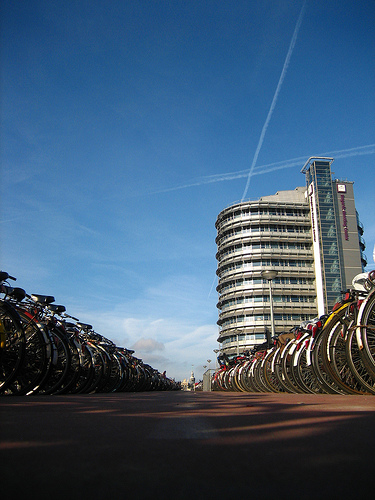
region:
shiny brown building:
[203, 178, 328, 330]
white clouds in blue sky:
[8, 15, 57, 67]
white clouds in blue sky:
[13, 61, 115, 142]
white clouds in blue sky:
[14, 130, 56, 178]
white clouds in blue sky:
[53, 146, 114, 198]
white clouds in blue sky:
[45, 223, 111, 279]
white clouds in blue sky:
[103, 279, 176, 335]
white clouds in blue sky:
[164, 242, 207, 295]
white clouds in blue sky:
[101, 178, 146, 238]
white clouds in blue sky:
[205, 123, 247, 161]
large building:
[212, 179, 319, 306]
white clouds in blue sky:
[13, 70, 46, 105]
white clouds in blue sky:
[121, 253, 173, 300]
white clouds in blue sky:
[150, 295, 196, 355]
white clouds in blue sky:
[94, 294, 145, 327]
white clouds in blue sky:
[43, 151, 89, 200]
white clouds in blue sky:
[150, 186, 182, 228]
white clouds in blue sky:
[170, 116, 235, 147]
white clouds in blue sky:
[234, 74, 299, 114]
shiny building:
[212, 183, 314, 316]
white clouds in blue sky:
[19, 45, 73, 118]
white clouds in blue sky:
[28, 138, 63, 179]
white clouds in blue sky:
[36, 207, 77, 244]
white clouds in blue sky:
[85, 262, 132, 294]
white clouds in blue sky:
[143, 261, 183, 308]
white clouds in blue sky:
[122, 305, 184, 352]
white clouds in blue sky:
[109, 59, 147, 109]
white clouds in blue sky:
[212, 72, 257, 111]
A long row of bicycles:
[1, 270, 179, 402]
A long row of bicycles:
[190, 265, 373, 392]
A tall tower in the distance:
[189, 370, 195, 383]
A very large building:
[214, 155, 368, 368]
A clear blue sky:
[1, 0, 372, 381]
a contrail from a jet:
[237, 5, 305, 202]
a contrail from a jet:
[143, 145, 373, 195]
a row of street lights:
[202, 269, 280, 378]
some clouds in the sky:
[78, 312, 222, 383]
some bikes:
[194, 266, 372, 391]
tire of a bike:
[346, 338, 363, 395]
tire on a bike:
[306, 334, 315, 395]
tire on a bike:
[275, 349, 284, 388]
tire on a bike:
[225, 360, 247, 385]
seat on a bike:
[30, 288, 49, 306]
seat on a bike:
[66, 315, 90, 330]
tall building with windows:
[210, 192, 277, 337]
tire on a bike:
[39, 330, 56, 393]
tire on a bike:
[232, 345, 248, 395]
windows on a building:
[252, 204, 309, 220]